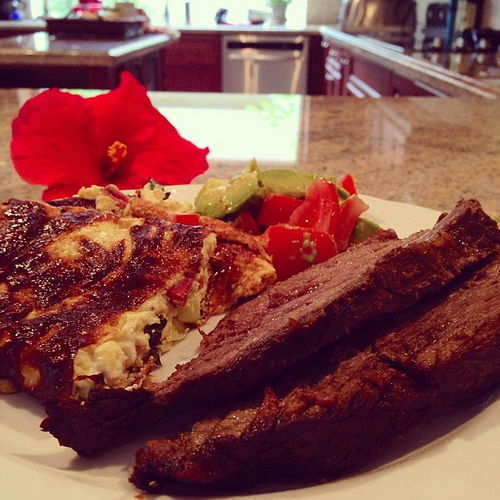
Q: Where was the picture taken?
A: In a kitchen.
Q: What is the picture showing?
A: Food.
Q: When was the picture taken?
A: During the day.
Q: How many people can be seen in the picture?
A: None.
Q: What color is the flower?
A: Red.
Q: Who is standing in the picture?
A: No one.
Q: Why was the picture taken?
A: To capture the food.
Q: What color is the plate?
A: White.